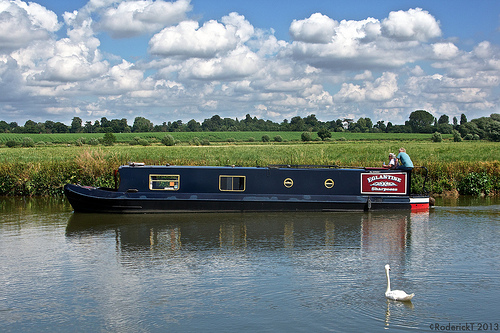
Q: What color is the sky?
A: Blue.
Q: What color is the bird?
A: White.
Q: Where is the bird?
A: In the water.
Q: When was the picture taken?
A: Daytime.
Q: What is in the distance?
A: Trees.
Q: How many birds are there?
A: One.